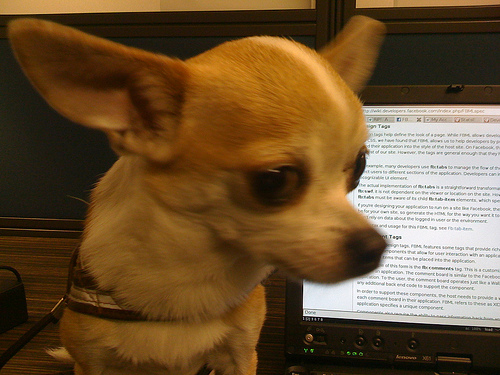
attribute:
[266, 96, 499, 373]
laptop — open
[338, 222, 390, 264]
nose — brown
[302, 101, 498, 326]
screen — white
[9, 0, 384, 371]
dog — brown , small 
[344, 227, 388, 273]
nose — black 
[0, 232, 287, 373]
surface — brown, wooden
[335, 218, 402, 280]
nose — black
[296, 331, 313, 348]
button — power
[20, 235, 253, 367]
collar — white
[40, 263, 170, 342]
dog collar — brown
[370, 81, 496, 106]
top — dark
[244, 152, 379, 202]
eyes — large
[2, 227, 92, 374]
desk — wood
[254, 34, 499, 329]
laptop — black 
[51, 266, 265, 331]
collar — brown 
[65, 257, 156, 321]
collar — brown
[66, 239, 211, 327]
collar — brown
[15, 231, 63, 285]
carpet — plaid